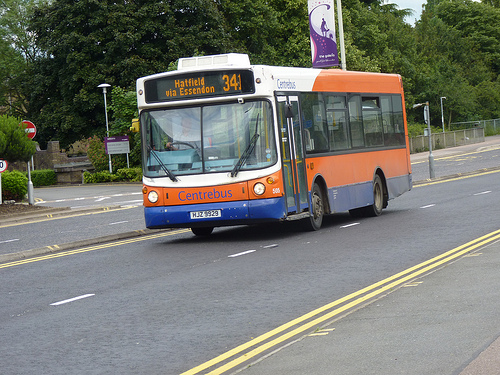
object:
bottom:
[143, 197, 286, 228]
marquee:
[155, 73, 242, 100]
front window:
[140, 105, 202, 178]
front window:
[203, 98, 277, 173]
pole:
[335, 0, 347, 70]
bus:
[136, 52, 414, 237]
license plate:
[189, 208, 223, 219]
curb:
[205, 232, 499, 373]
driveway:
[0, 145, 499, 373]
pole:
[103, 88, 113, 173]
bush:
[2, 170, 31, 199]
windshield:
[200, 100, 279, 173]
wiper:
[146, 143, 177, 182]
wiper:
[228, 112, 262, 178]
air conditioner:
[175, 51, 250, 69]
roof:
[136, 65, 399, 81]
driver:
[164, 116, 202, 149]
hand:
[163, 141, 171, 148]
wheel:
[164, 141, 196, 151]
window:
[363, 110, 384, 146]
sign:
[18, 119, 38, 140]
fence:
[409, 126, 479, 153]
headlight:
[252, 181, 266, 195]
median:
[49, 293, 96, 306]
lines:
[206, 233, 499, 374]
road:
[0, 134, 499, 373]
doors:
[276, 95, 299, 213]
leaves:
[363, 47, 373, 53]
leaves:
[298, 59, 303, 63]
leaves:
[57, 107, 67, 111]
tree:
[0, 113, 40, 163]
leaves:
[63, 80, 69, 85]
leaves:
[80, 69, 89, 75]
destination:
[164, 77, 215, 98]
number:
[222, 74, 231, 92]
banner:
[307, 0, 339, 68]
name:
[177, 187, 232, 200]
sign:
[104, 135, 131, 154]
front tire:
[307, 177, 324, 230]